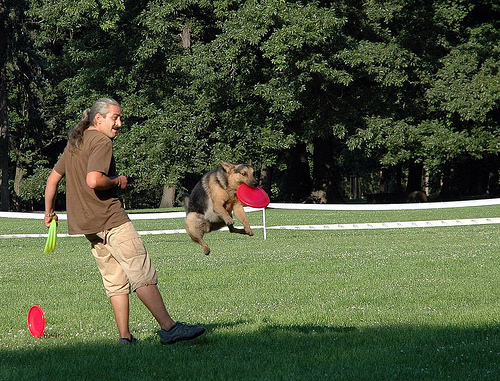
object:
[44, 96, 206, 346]
man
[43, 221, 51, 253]
frisbee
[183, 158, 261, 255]
dog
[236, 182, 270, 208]
frisbee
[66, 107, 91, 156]
ponytail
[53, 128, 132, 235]
shirt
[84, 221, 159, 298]
shorts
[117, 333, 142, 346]
shoes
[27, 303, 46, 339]
frisbee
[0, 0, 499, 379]
field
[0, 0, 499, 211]
trees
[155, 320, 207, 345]
foot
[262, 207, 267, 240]
pole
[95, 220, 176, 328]
legs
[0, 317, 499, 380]
shadow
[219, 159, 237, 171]
ears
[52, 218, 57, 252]
frisbees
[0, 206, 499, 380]
grass